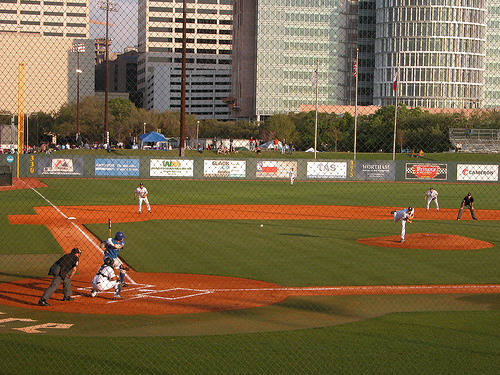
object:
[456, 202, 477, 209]
hands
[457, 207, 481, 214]
knees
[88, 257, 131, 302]
catcher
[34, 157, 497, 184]
signs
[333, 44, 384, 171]
pole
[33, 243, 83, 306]
man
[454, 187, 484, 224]
man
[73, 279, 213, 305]
white lines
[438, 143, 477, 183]
ground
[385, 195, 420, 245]
pitcher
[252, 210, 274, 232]
ball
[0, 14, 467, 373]
field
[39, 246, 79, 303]
unmpire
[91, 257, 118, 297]
catcher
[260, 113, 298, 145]
tree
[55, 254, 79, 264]
shirt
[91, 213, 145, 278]
batter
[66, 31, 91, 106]
pole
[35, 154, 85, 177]
sign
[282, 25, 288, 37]
window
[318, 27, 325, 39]
window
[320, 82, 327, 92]
window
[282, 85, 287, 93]
window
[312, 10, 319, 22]
window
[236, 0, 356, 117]
building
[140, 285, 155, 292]
home plate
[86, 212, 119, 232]
bat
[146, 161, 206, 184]
banner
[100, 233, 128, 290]
man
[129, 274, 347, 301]
lines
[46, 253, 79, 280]
vest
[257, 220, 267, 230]
pitch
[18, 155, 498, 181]
wall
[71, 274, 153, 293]
box